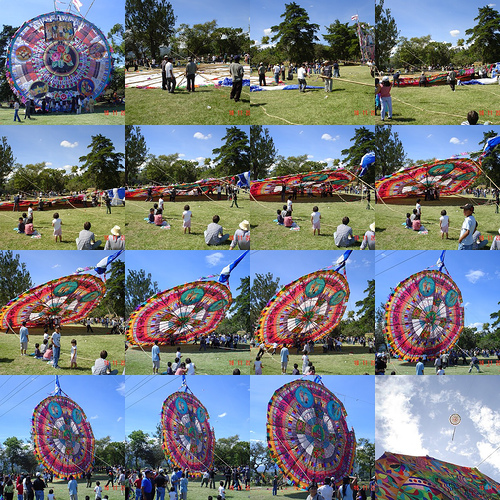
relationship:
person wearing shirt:
[150, 343, 164, 374] [151, 347, 160, 363]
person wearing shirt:
[279, 342, 291, 374] [279, 347, 291, 362]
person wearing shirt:
[414, 356, 426, 375] [415, 363, 426, 375]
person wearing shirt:
[19, 322, 30, 356] [17, 327, 29, 344]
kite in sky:
[449, 413, 461, 441] [374, 375, 499, 483]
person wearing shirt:
[164, 57, 179, 93] [164, 63, 174, 78]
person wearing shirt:
[296, 64, 309, 91] [296, 67, 308, 79]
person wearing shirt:
[49, 325, 64, 369] [49, 329, 63, 347]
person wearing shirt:
[456, 203, 479, 250] [458, 217, 476, 245]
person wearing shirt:
[272, 63, 281, 84] [272, 65, 281, 73]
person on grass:
[164, 57, 179, 93] [123, 87, 249, 125]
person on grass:
[272, 63, 281, 84] [252, 63, 374, 125]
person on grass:
[456, 203, 479, 250] [375, 193, 499, 248]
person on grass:
[150, 343, 164, 374] [123, 339, 250, 376]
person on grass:
[414, 356, 426, 375] [374, 353, 499, 373]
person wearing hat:
[103, 225, 126, 249] [110, 225, 121, 237]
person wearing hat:
[228, 219, 252, 251] [238, 220, 250, 231]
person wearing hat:
[358, 220, 377, 249] [369, 221, 375, 231]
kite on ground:
[5, 12, 112, 112] [7, 101, 125, 124]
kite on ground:
[374, 135, 499, 204] [375, 193, 499, 248]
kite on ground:
[125, 251, 251, 346] [123, 339, 250, 376]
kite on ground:
[254, 251, 354, 349] [250, 342, 376, 375]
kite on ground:
[383, 250, 466, 364] [374, 353, 499, 373]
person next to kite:
[150, 343, 164, 374] [125, 251, 251, 346]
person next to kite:
[279, 342, 291, 374] [254, 251, 354, 349]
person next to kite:
[19, 322, 30, 356] [0, 251, 126, 329]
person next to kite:
[316, 476, 335, 499] [266, 377, 357, 490]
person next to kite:
[49, 325, 64, 369] [0, 251, 126, 329]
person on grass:
[202, 214, 228, 246] [125, 199, 250, 251]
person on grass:
[228, 219, 252, 251] [125, 199, 250, 251]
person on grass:
[331, 217, 357, 247] [249, 195, 377, 251]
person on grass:
[358, 220, 377, 249] [249, 195, 377, 251]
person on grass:
[412, 215, 423, 232] [375, 193, 499, 248]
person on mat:
[154, 208, 165, 225] [161, 223, 171, 232]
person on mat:
[24, 220, 34, 234] [33, 230, 41, 241]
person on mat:
[283, 212, 292, 229] [290, 226, 301, 234]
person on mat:
[412, 215, 423, 232] [417, 228, 427, 239]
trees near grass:
[1, 136, 124, 195] [0, 208, 128, 250]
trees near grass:
[125, 126, 250, 185] [125, 199, 250, 251]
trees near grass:
[252, 126, 376, 186] [249, 195, 377, 251]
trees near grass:
[250, 3, 375, 66] [252, 63, 374, 125]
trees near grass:
[376, 0, 500, 72] [378, 72, 499, 123]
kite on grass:
[126, 177, 226, 200] [125, 199, 250, 251]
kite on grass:
[0, 192, 86, 209] [0, 208, 128, 250]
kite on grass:
[373, 72, 476, 86] [378, 72, 499, 123]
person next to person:
[183, 57, 197, 93] [164, 57, 179, 93]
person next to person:
[159, 53, 169, 89] [164, 57, 179, 93]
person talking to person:
[159, 53, 169, 89] [183, 57, 197, 93]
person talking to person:
[164, 57, 179, 93] [183, 57, 197, 93]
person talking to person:
[164, 57, 179, 93] [159, 53, 169, 89]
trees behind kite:
[376, 0, 500, 72] [373, 72, 476, 86]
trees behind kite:
[1, 136, 124, 195] [0, 192, 86, 209]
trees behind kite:
[125, 126, 250, 185] [126, 177, 226, 200]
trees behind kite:
[252, 126, 376, 186] [250, 167, 360, 196]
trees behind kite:
[376, 128, 412, 178] [374, 135, 499, 204]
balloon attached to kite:
[97, 251, 122, 274] [0, 251, 126, 329]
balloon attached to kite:
[219, 252, 248, 281] [125, 251, 251, 346]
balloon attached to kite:
[336, 250, 353, 266] [254, 251, 354, 349]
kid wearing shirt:
[438, 209, 450, 240] [438, 215, 452, 230]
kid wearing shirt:
[306, 205, 326, 235] [311, 211, 322, 225]